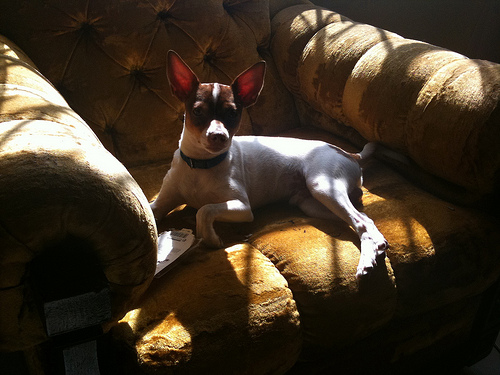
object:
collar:
[175, 149, 228, 171]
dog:
[148, 51, 388, 280]